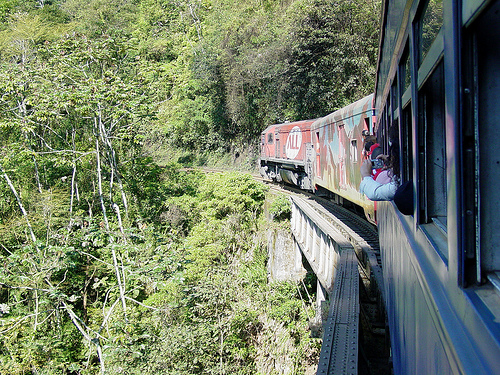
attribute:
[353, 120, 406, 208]
person — leaning, hanging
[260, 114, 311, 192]
train — red, colorful, logo, blue, old\, brown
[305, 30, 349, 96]
tree — green, tall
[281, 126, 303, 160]
circle — white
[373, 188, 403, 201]
sleeve — blue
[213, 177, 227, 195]
fence — wood